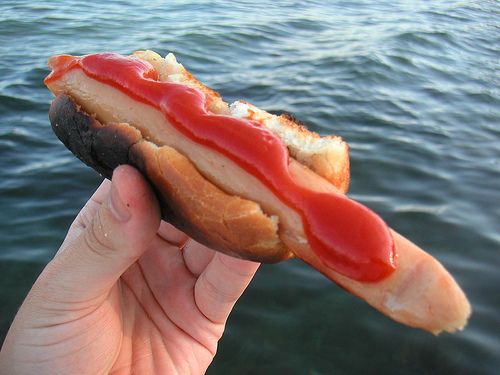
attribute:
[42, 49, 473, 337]
footlong — long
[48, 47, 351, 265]
bun — toasted, marked, burnt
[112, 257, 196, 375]
palm — wrinkled, creased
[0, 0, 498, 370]
water — blue, dark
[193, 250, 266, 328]
pinky — lined